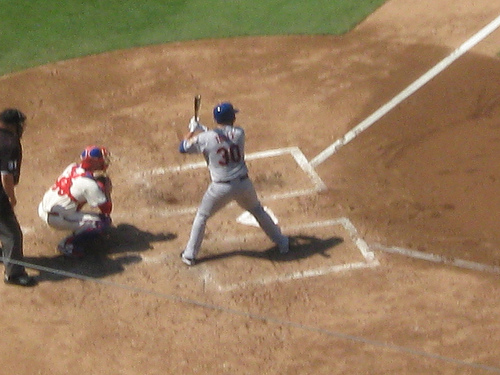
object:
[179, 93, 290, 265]
baseball player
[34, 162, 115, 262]
uniform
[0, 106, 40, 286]
athlete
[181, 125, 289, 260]
uniform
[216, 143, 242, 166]
number 30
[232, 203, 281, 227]
home plate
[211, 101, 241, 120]
baseball hat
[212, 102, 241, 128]
player's head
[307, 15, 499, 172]
line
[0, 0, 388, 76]
grass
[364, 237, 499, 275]
line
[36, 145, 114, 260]
baseball catcher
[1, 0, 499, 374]
field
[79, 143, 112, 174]
hat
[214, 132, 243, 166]
red print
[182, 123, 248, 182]
baseball jersey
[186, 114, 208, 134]
gloves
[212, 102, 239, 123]
hat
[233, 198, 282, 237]
base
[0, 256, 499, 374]
cable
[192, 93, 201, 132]
bat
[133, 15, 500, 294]
lines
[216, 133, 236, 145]
writing